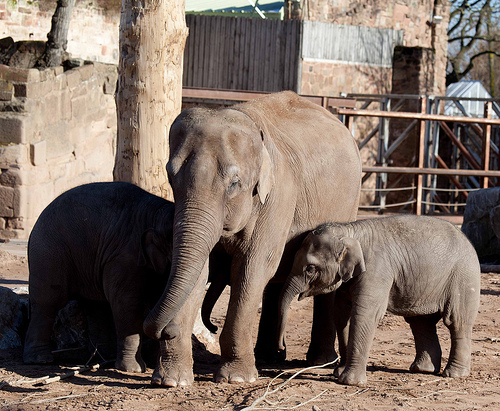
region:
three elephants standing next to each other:
[13, 87, 429, 381]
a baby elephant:
[265, 199, 470, 409]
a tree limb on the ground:
[241, 340, 343, 409]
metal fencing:
[113, 73, 490, 184]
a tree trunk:
[109, 5, 224, 208]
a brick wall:
[1, 47, 113, 219]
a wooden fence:
[98, 13, 315, 86]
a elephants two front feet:
[100, 346, 262, 403]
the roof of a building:
[414, 78, 490, 153]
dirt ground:
[80, 340, 488, 409]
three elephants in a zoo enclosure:
[9, 80, 497, 402]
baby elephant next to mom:
[269, 209, 490, 394]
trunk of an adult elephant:
[144, 217, 214, 349]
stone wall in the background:
[3, 57, 121, 192]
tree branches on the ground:
[226, 357, 346, 409]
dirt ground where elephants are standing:
[366, 380, 489, 409]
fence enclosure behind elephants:
[363, 107, 498, 191]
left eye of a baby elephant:
[297, 255, 327, 280]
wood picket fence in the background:
[187, 8, 304, 96]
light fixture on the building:
[426, 8, 447, 35]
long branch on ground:
[253, 358, 338, 407]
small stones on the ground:
[480, 321, 498, 366]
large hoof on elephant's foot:
[127, 370, 217, 391]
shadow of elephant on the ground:
[22, 157, 193, 353]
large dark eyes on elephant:
[215, 157, 265, 202]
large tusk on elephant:
[138, 163, 251, 369]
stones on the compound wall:
[34, 92, 104, 151]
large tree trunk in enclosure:
[98, 6, 208, 94]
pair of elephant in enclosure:
[145, 75, 493, 387]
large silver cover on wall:
[296, 10, 424, 82]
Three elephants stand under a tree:
[8, 88, 473, 386]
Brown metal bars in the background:
[336, 95, 494, 253]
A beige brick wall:
[7, 13, 134, 274]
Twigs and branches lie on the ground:
[11, 353, 343, 407]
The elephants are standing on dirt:
[48, 126, 480, 404]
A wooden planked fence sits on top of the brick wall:
[178, 10, 419, 105]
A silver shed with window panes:
[441, 67, 496, 122]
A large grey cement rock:
[441, 176, 496, 277]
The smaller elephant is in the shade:
[18, 150, 215, 371]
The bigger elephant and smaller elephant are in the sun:
[158, 105, 474, 387]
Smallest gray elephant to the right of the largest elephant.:
[276, 206, 480, 386]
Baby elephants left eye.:
[305, 262, 316, 272]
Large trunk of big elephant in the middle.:
[142, 169, 225, 338]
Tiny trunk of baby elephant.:
[276, 270, 305, 350]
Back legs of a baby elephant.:
[400, 298, 479, 380]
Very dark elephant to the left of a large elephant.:
[22, 179, 238, 369]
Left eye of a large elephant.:
[230, 166, 242, 192]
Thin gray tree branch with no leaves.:
[228, 357, 370, 409]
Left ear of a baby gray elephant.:
[337, 237, 366, 282]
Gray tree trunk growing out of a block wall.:
[38, 0, 76, 70]